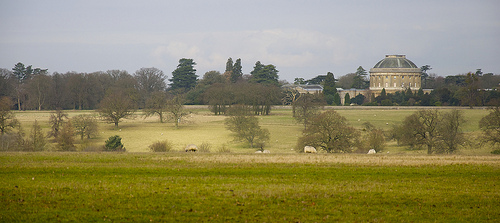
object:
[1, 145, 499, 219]
grass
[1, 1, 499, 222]
photo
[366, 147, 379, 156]
animals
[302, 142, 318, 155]
animals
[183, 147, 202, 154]
animals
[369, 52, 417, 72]
roof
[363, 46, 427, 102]
building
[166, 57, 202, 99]
tree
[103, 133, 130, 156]
tree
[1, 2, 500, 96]
day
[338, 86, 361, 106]
entrance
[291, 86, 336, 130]
trees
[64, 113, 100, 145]
trees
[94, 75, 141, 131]
trees